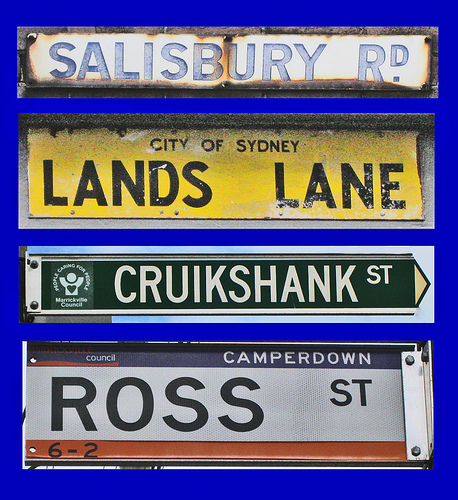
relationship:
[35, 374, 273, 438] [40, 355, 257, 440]
ross in large letters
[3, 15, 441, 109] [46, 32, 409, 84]
worn sign says salisbury rd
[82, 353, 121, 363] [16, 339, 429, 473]
word council on sign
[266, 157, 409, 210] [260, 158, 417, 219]
word lane in black letters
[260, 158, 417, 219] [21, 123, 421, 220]
black letters on yellow sign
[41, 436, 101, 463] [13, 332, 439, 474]
numbers on bottom sign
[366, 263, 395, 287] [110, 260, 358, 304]
st after word cruikshank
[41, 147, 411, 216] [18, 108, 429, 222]
lettering on sign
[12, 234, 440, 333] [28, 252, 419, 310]
street sign for cruikshank st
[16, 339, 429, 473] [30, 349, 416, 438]
sign for ross st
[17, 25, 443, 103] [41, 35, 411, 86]
street sign for salisbury rd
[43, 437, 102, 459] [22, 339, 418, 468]
numbering on sign